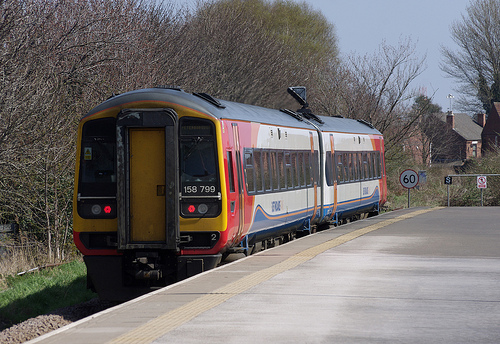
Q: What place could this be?
A: It is a sidewalk.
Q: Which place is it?
A: It is a sidewalk.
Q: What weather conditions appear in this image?
A: It is clear.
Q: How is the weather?
A: It is clear.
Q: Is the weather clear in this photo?
A: Yes, it is clear.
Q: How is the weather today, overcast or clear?
A: It is clear.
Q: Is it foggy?
A: No, it is clear.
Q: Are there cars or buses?
A: No, there are no cars or buses.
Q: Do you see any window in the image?
A: Yes, there is a window.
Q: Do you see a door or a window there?
A: Yes, there is a window.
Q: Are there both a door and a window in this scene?
A: Yes, there are both a window and a door.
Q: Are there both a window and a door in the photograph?
A: Yes, there are both a window and a door.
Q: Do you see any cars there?
A: No, there are no cars.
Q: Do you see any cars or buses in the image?
A: No, there are no cars or buses.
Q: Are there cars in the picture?
A: No, there are no cars.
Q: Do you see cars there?
A: No, there are no cars.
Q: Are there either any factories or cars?
A: No, there are no cars or factories.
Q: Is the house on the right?
A: Yes, the house is on the right of the image.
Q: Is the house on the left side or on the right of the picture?
A: The house is on the right of the image.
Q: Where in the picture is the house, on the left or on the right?
A: The house is on the right of the image.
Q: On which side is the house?
A: The house is on the right of the image.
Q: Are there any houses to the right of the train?
A: Yes, there is a house to the right of the train.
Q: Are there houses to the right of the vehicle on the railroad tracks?
A: Yes, there is a house to the right of the train.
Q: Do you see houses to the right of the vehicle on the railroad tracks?
A: Yes, there is a house to the right of the train.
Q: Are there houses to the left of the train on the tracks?
A: No, the house is to the right of the train.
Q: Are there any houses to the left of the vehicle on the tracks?
A: No, the house is to the right of the train.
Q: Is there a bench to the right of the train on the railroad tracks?
A: No, there is a house to the right of the train.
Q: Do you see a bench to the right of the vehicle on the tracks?
A: No, there is a house to the right of the train.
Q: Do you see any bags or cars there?
A: No, there are no cars or bags.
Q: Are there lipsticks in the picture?
A: No, there are no lipsticks.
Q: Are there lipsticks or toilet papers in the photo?
A: No, there are no lipsticks or toilet papers.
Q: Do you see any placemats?
A: No, there are no placemats.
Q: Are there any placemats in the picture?
A: No, there are no placemats.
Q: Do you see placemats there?
A: No, there are no placemats.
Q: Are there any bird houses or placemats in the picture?
A: No, there are no placemats or bird houses.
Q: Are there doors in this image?
A: Yes, there is a door.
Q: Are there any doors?
A: Yes, there is a door.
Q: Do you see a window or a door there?
A: Yes, there is a door.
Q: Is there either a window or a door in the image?
A: Yes, there is a door.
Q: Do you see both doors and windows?
A: Yes, there are both a door and a window.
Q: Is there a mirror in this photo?
A: No, there are no mirrors.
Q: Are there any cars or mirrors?
A: No, there are no mirrors or cars.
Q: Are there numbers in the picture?
A: Yes, there are numbers.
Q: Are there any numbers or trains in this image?
A: Yes, there are numbers.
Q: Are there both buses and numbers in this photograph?
A: No, there are numbers but no buses.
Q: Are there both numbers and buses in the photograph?
A: No, there are numbers but no buses.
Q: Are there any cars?
A: No, there are no cars.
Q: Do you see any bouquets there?
A: No, there are no bouquets.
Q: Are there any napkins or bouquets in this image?
A: No, there are no bouquets or napkins.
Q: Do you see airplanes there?
A: No, there are no airplanes.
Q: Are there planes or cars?
A: No, there are no planes or cars.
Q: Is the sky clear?
A: Yes, the sky is clear.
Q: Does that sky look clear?
A: Yes, the sky is clear.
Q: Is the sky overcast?
A: No, the sky is clear.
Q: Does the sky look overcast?
A: No, the sky is clear.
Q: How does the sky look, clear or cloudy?
A: The sky is clear.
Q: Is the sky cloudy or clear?
A: The sky is clear.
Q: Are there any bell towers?
A: No, there are no bell towers.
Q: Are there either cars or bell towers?
A: No, there are no bell towers or cars.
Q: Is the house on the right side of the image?
A: Yes, the house is on the right of the image.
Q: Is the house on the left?
A: No, the house is on the right of the image.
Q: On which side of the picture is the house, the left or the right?
A: The house is on the right of the image.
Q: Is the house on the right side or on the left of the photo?
A: The house is on the right of the image.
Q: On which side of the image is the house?
A: The house is on the right of the image.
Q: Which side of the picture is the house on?
A: The house is on the right of the image.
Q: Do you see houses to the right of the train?
A: Yes, there is a house to the right of the train.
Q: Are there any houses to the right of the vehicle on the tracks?
A: Yes, there is a house to the right of the train.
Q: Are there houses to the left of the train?
A: No, the house is to the right of the train.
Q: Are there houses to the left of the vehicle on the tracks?
A: No, the house is to the right of the train.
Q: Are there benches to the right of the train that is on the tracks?
A: No, there is a house to the right of the train.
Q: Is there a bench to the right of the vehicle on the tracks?
A: No, there is a house to the right of the train.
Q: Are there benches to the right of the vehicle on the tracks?
A: No, there is a house to the right of the train.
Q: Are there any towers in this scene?
A: No, there are no towers.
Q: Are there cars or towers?
A: No, there are no towers or cars.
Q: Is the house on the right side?
A: Yes, the house is on the right of the image.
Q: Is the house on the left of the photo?
A: No, the house is on the right of the image.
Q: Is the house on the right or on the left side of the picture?
A: The house is on the right of the image.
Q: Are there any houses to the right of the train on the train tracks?
A: Yes, there is a house to the right of the train.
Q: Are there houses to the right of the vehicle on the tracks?
A: Yes, there is a house to the right of the train.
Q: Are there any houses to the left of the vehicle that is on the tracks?
A: No, the house is to the right of the train.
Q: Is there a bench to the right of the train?
A: No, there is a house to the right of the train.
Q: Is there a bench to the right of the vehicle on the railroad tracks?
A: No, there is a house to the right of the train.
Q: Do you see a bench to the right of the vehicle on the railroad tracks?
A: No, there is a house to the right of the train.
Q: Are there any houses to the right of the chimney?
A: Yes, there is a house to the right of the chimney.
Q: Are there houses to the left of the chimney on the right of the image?
A: No, the house is to the right of the chimney.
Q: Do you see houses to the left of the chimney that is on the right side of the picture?
A: No, the house is to the right of the chimney.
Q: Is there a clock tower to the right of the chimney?
A: No, there is a house to the right of the chimney.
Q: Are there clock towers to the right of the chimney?
A: No, there is a house to the right of the chimney.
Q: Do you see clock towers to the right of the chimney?
A: No, there is a house to the right of the chimney.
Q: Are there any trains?
A: Yes, there is a train.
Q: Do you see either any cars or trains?
A: Yes, there is a train.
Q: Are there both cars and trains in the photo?
A: No, there is a train but no cars.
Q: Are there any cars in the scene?
A: No, there are no cars.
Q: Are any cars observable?
A: No, there are no cars.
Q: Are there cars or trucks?
A: No, there are no cars or trucks.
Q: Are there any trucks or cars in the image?
A: No, there are no cars or trucks.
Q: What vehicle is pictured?
A: The vehicle is a train.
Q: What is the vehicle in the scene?
A: The vehicle is a train.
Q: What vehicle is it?
A: The vehicle is a train.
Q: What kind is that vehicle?
A: This is a train.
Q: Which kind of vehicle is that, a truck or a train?
A: This is a train.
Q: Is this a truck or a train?
A: This is a train.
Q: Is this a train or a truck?
A: This is a train.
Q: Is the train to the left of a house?
A: Yes, the train is to the left of a house.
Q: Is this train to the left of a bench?
A: No, the train is to the left of a house.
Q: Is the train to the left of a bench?
A: No, the train is to the left of a house.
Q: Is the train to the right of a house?
A: No, the train is to the left of a house.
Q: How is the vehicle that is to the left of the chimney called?
A: The vehicle is a train.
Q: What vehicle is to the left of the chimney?
A: The vehicle is a train.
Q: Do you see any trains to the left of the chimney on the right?
A: Yes, there is a train to the left of the chimney.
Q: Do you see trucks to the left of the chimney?
A: No, there is a train to the left of the chimney.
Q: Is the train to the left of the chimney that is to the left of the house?
A: Yes, the train is to the left of the chimney.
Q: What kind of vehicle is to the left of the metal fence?
A: The vehicle is a train.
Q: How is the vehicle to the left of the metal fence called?
A: The vehicle is a train.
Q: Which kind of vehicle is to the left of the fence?
A: The vehicle is a train.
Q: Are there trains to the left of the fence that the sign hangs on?
A: Yes, there is a train to the left of the fence.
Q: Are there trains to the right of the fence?
A: No, the train is to the left of the fence.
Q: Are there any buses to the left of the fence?
A: No, there is a train to the left of the fence.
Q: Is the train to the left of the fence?
A: Yes, the train is to the left of the fence.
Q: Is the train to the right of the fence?
A: No, the train is to the left of the fence.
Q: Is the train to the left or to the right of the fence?
A: The train is to the left of the fence.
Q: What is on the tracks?
A: The train is on the tracks.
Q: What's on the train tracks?
A: The train is on the tracks.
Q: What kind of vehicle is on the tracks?
A: The vehicle is a train.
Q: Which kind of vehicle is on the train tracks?
A: The vehicle is a train.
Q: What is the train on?
A: The train is on the tracks.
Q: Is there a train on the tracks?
A: Yes, there is a train on the tracks.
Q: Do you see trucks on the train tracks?
A: No, there is a train on the train tracks.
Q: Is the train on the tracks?
A: Yes, the train is on the tracks.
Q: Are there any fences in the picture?
A: Yes, there is a fence.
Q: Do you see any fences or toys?
A: Yes, there is a fence.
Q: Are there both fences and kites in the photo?
A: No, there is a fence but no kites.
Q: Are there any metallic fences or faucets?
A: Yes, there is a metal fence.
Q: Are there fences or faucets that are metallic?
A: Yes, the fence is metallic.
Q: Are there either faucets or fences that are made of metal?
A: Yes, the fence is made of metal.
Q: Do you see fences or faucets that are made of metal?
A: Yes, the fence is made of metal.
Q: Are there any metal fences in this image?
A: Yes, there is a metal fence.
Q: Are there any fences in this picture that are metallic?
A: Yes, there is a fence that is metallic.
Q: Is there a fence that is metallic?
A: Yes, there is a fence that is metallic.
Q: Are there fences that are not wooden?
A: Yes, there is a metallic fence.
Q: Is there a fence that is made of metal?
A: Yes, there is a fence that is made of metal.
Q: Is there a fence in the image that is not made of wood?
A: Yes, there is a fence that is made of metal.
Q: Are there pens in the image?
A: No, there are no pens.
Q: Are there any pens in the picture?
A: No, there are no pens.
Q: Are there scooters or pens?
A: No, there are no pens or scooters.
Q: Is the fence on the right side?
A: Yes, the fence is on the right of the image.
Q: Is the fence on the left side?
A: No, the fence is on the right of the image.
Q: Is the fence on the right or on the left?
A: The fence is on the right of the image.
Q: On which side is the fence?
A: The fence is on the right of the image.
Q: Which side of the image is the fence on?
A: The fence is on the right of the image.